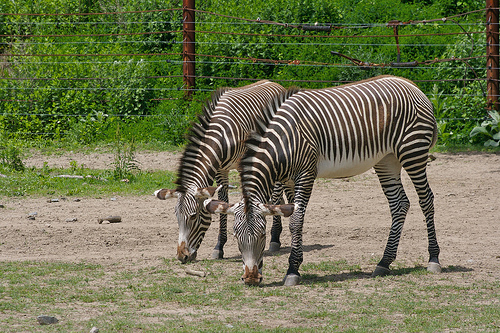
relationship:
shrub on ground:
[93, 49, 162, 114] [2, 136, 499, 331]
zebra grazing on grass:
[233, 59, 443, 281] [22, 250, 100, 301]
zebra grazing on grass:
[150, 67, 287, 265] [22, 250, 100, 301]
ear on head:
[152, 184, 179, 198] [159, 178, 218, 245]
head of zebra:
[159, 178, 218, 245] [249, 69, 496, 307]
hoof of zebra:
[280, 266, 303, 287] [205, 73, 442, 287]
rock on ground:
[36, 312, 63, 328] [40, 322, 74, 331]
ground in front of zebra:
[40, 322, 74, 331] [223, 67, 458, 298]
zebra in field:
[150, 67, 287, 265] [0, 145, 499, 331]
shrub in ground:
[9, 74, 132, 144] [2, 114, 495, 321]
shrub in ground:
[112, 72, 219, 146] [2, 114, 495, 321]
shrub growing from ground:
[49, 112, 171, 144] [2, 136, 499, 331]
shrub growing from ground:
[102, 139, 151, 180] [2, 114, 495, 321]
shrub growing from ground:
[440, 16, 469, 81] [459, 162, 489, 226]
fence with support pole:
[26, 27, 492, 179] [145, 27, 441, 108]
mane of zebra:
[237, 85, 302, 211] [208, 64, 457, 287]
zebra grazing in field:
[233, 59, 443, 281] [34, 285, 478, 330]